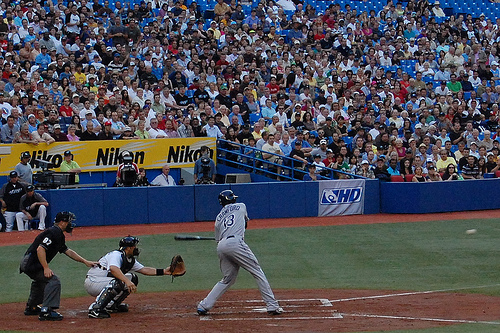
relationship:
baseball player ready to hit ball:
[196, 189, 283, 317] [462, 226, 477, 237]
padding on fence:
[43, 177, 497, 217] [48, 175, 495, 222]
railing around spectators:
[217, 139, 367, 182] [2, 2, 499, 181]